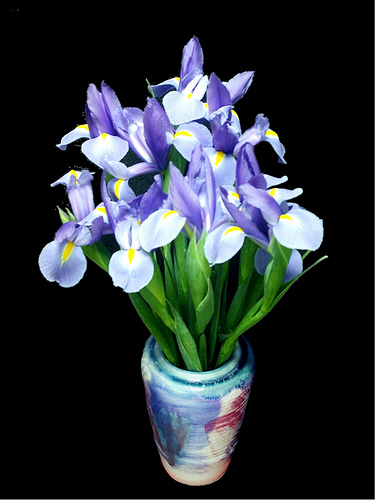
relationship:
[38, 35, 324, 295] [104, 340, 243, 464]
flower in pot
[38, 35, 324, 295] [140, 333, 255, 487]
flower in vase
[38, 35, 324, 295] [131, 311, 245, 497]
flower are in jar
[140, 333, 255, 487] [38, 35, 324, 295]
vase containing flower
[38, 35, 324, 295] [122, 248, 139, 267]
flower with center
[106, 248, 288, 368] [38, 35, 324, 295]
stems of flower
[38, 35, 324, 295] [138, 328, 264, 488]
flower in vase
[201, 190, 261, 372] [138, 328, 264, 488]
flower in vase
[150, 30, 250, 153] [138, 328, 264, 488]
flower in vase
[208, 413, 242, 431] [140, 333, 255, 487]
plum color on vase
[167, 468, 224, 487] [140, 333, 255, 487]
pink on bottom of vase